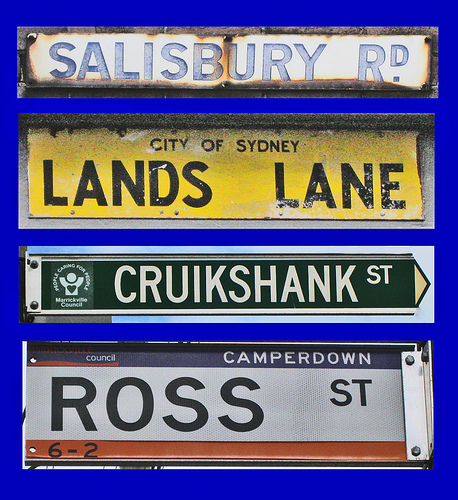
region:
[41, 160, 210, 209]
The word LANDS.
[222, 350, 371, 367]
The word CAMPERDOWN.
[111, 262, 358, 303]
The word CRUIKSHANK.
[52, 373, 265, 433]
ROSS in very large letters.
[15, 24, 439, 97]
A worn sign that says SALISBURY RD.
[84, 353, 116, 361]
The word council on the red white and blue sign.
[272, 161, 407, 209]
The word LANE in black letters on a yellow sign.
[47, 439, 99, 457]
The numbers 6-2 on the bottom sign.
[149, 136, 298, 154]
CITY OF SYDNEY on a yellow sign.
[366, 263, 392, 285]
ST after the word CRUIKSHANK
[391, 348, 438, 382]
silver screw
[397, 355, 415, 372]
silver screw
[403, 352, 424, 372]
silver screw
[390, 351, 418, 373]
silver screw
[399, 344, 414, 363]
silver screw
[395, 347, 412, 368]
silver screw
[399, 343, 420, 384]
silver screw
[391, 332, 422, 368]
silver screw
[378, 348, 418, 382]
silver screw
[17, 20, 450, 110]
Sign is rusty and old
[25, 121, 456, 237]
The lettering on this sign is fading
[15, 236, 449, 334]
Street sign for Cruikshank st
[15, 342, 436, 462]
Sign for Ross St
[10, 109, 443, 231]
Lands lane road sign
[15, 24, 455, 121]
Salisbury rd street sign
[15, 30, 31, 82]
Rust on side of sign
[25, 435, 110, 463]
Numbering on street sign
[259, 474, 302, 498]
Blue background behind signs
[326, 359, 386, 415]
Abbreviation for the word street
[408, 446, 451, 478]
silver screw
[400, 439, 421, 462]
silver screw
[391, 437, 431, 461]
silver screw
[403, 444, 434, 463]
silver screw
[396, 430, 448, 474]
silver screw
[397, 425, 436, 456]
silver screw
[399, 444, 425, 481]
silver screw